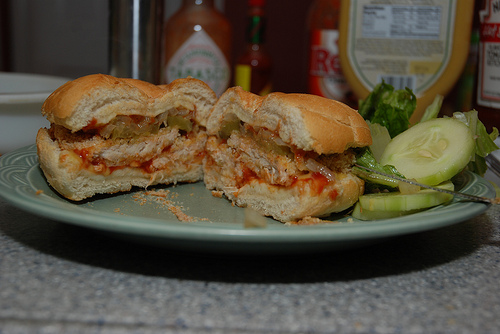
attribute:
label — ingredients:
[342, 3, 459, 99]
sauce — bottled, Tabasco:
[159, 2, 231, 97]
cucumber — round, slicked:
[373, 101, 470, 193]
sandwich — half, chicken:
[59, 57, 215, 217]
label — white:
[162, 30, 229, 92]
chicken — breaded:
[227, 123, 314, 185]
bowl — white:
[1, 64, 72, 153]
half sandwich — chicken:
[203, 86, 370, 221]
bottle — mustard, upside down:
[345, 0, 469, 117]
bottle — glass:
[157, 4, 247, 106]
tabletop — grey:
[1, 195, 496, 332]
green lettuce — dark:
[356, 75, 417, 142]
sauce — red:
[221, 129, 343, 204]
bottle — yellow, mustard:
[319, 8, 486, 128]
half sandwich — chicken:
[26, 68, 234, 218]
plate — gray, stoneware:
[0, 144, 495, 261]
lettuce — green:
[357, 72, 422, 132]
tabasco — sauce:
[165, 14, 225, 83]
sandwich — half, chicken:
[23, 72, 224, 212]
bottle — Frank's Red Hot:
[152, 8, 235, 102]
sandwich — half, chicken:
[200, 87, 370, 221]